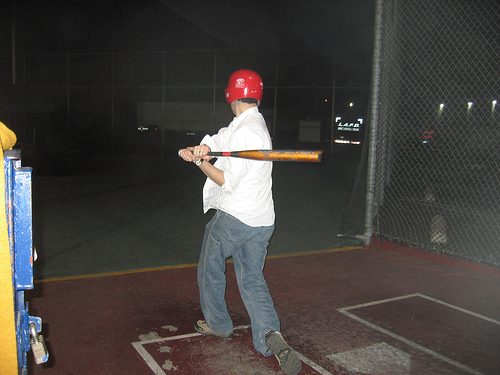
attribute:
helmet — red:
[211, 48, 290, 135]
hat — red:
[220, 66, 264, 105]